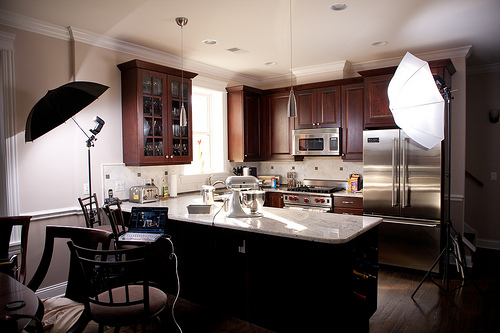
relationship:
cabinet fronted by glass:
[116, 54, 201, 168] [143, 78, 192, 158]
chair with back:
[68, 238, 170, 332] [71, 239, 155, 319]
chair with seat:
[68, 238, 170, 332] [90, 278, 170, 323]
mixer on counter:
[221, 172, 268, 220] [110, 190, 385, 244]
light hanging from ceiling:
[175, 13, 195, 127] [0, 4, 499, 87]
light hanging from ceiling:
[284, 1, 304, 117] [0, 4, 499, 87]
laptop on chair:
[119, 204, 173, 244] [104, 195, 154, 264]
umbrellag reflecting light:
[382, 44, 477, 305] [19, 89, 229, 209]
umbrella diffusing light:
[21, 77, 111, 224] [19, 89, 229, 209]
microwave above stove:
[290, 125, 340, 154] [282, 175, 346, 205]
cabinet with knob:
[116, 54, 201, 168] [164, 153, 169, 157]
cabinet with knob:
[116, 54, 201, 168] [170, 153, 175, 158]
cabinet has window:
[116, 54, 201, 168] [144, 76, 164, 153]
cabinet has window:
[116, 54, 201, 168] [173, 82, 188, 151]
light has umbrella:
[19, 89, 229, 209] [21, 77, 111, 224]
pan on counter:
[188, 203, 212, 214] [110, 190, 385, 244]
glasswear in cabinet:
[171, 123, 188, 138] [116, 54, 201, 168]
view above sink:
[192, 87, 225, 180] [207, 176, 240, 198]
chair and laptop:
[68, 238, 170, 332] [119, 204, 173, 244]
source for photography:
[21, 76, 113, 269] [8, 1, 495, 331]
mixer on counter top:
[221, 172, 268, 220] [110, 190, 385, 244]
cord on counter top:
[210, 195, 227, 232] [110, 190, 385, 244]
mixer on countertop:
[221, 172, 268, 220] [110, 190, 385, 244]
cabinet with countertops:
[241, 245, 338, 322] [120, 190, 383, 246]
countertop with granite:
[115, 182, 386, 233] [114, 189, 381, 247]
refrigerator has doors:
[358, 131, 442, 269] [364, 129, 446, 212]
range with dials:
[284, 175, 354, 208] [286, 194, 331, 202]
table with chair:
[3, 267, 43, 328] [29, 221, 121, 330]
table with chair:
[3, 267, 43, 328] [2, 215, 38, 274]